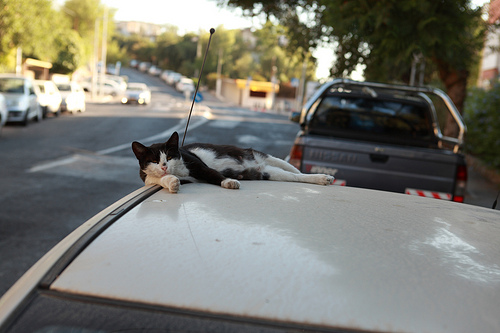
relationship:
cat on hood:
[125, 128, 337, 195] [1, 168, 496, 329]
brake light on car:
[455, 158, 469, 197] [286, 80, 468, 202]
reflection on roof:
[425, 212, 499, 284] [48, 174, 499, 331]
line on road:
[24, 99, 213, 176] [0, 62, 298, 296]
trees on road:
[0, 1, 107, 107] [5, 50, 298, 327]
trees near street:
[1, 1, 498, 152] [0, 61, 301, 331]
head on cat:
[129, 123, 174, 163] [131, 136, 298, 207]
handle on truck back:
[368, 149, 388, 164] [298, 134, 470, 199]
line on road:
[32, 144, 126, 166] [5, 50, 298, 327]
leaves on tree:
[43, 26, 53, 40] [1, 2, 81, 74]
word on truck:
[308, 144, 360, 163] [288, 79, 468, 203]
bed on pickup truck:
[318, 127, 458, 151] [288, 75, 470, 204]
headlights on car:
[116, 90, 148, 105] [308, 78, 405, 174]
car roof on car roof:
[1, 180, 496, 331] [1, 180, 496, 331]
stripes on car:
[404, 185, 454, 202] [286, 80, 468, 202]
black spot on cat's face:
[141, 146, 181, 166] [140, 140, 184, 178]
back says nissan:
[292, 135, 469, 200] [304, 147, 369, 164]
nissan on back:
[304, 147, 369, 164] [292, 135, 469, 200]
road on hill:
[5, 50, 298, 327] [66, 0, 332, 105]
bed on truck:
[318, 127, 458, 151] [288, 79, 468, 203]